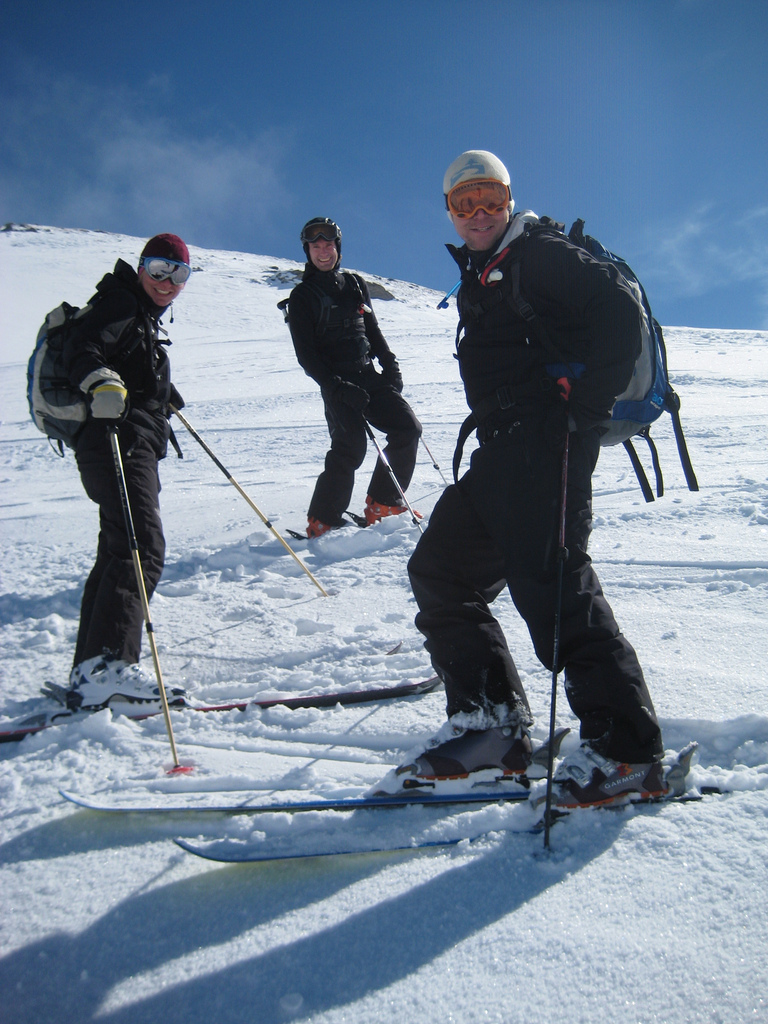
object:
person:
[70, 147, 665, 800]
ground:
[0, 221, 768, 1023]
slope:
[4, 216, 768, 1024]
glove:
[79, 367, 128, 419]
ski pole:
[172, 408, 332, 596]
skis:
[57, 728, 701, 865]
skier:
[288, 216, 423, 539]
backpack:
[26, 302, 183, 458]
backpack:
[277, 272, 372, 377]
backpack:
[509, 216, 699, 504]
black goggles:
[139, 257, 192, 286]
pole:
[543, 396, 569, 849]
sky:
[0, 0, 767, 331]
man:
[69, 233, 192, 722]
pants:
[74, 437, 167, 665]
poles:
[108, 421, 195, 777]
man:
[407, 157, 666, 816]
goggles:
[448, 177, 510, 220]